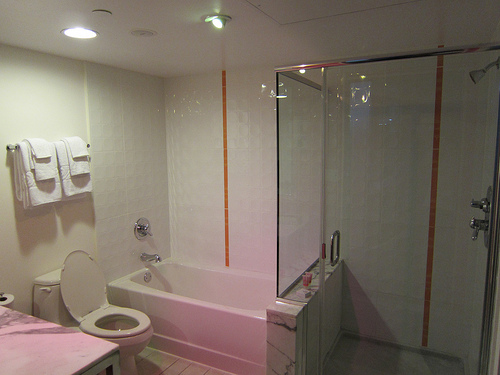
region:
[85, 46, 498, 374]
Shiny white tiles on the wall.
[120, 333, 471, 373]
Tan floor tiles.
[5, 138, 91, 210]
White towels hanging from a towel rack.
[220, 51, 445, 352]
Two orange stripes on the wall tile.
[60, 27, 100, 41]
A recessed light on the ceiling.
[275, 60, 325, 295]
Glass divider between the bathtub and shower.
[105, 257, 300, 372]
A white bathtub.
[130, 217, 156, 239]
A silver single bathtub handle.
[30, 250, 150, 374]
A white toilet with an open lid.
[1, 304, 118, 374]
Bathroom vanity countertop.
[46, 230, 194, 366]
a bathroom toilet that is white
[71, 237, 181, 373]
a toilet in the bathroom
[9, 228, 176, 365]
a toilet that is white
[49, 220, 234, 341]
a white bathroom toilet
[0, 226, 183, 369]
a toilet with lid up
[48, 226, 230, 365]
toilet with seat down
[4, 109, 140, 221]
towels hanging on the wall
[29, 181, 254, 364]
a toilet in the bathroom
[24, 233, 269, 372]
a white toilet with lid up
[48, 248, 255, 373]
a white toilet with seat down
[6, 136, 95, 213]
Towels on a silver rack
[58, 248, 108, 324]
A white toilet seat lid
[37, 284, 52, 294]
A white toilet flush handle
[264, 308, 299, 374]
A marble wall tile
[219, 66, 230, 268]
A row of orange wall tiles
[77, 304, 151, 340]
A white toilet seat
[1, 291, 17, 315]
A roll of toilet paper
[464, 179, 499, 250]
Chrome shower valves on the wall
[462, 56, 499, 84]
A chrome shower head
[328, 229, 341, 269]
A chrome door handle on a glass door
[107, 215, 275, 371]
small white bath tub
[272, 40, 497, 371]
a glass enclosed shower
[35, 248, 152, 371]
white toilet next to a tub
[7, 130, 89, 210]
assortment of white towels in a bathroom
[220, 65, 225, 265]
orange wall tiles arranged in a line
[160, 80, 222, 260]
wall covered in white tiles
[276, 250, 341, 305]
small cultured marble shelf in a shower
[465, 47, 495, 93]
metal showerhead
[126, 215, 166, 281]
silver colored metal tub fixtures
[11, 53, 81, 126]
open wall not covered in tiles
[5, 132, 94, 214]
White towels on a bar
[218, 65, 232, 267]
A line of orange tile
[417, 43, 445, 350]
A line of orange tile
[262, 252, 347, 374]
A marble dividing wall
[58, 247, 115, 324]
A toilet with the cover up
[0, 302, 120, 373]
A black and white countertop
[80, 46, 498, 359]
White tile on the walls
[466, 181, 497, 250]
Silver colored shower fixtures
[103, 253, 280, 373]
A white rectangular bathtub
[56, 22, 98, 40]
A bright light in the ceiling